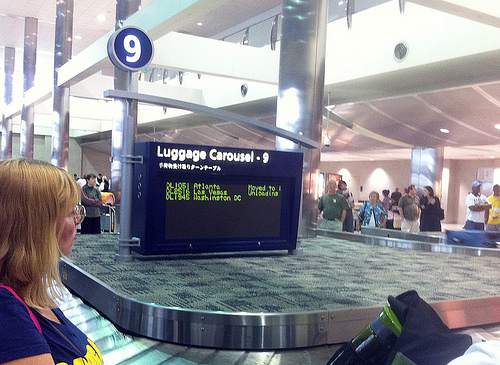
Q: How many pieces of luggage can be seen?
A: One.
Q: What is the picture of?
A: A luggage carousel.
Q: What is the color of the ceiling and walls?
A: White.